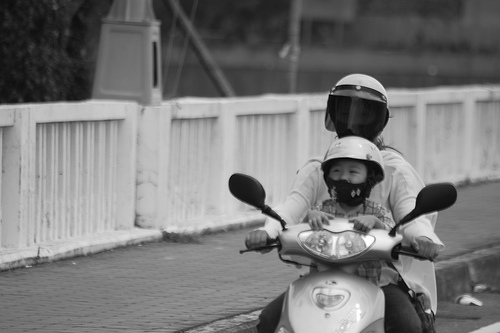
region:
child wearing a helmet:
[313, 134, 385, 209]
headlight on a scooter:
[295, 226, 377, 267]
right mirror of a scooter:
[223, 169, 288, 230]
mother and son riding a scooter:
[238, 68, 450, 317]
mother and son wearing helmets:
[321, 66, 391, 206]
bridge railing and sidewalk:
[35, 100, 224, 292]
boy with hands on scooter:
[305, 137, 390, 236]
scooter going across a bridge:
[220, 46, 460, 327]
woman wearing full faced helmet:
[320, 67, 392, 139]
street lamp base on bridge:
[87, 3, 171, 109]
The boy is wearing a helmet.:
[311, 137, 391, 211]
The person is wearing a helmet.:
[316, 67, 393, 135]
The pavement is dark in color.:
[77, 274, 158, 316]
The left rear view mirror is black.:
[415, 179, 461, 218]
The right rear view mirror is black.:
[222, 167, 269, 212]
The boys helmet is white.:
[317, 132, 391, 171]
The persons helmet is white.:
[326, 64, 387, 101]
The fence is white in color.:
[18, 112, 145, 242]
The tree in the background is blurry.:
[7, 11, 77, 85]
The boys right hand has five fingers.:
[303, 210, 335, 230]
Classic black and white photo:
[7, 6, 484, 326]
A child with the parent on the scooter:
[201, 70, 463, 332]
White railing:
[3, 83, 495, 265]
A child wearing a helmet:
[318, 133, 391, 209]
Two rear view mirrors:
[215, 162, 461, 226]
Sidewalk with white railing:
[6, 173, 495, 327]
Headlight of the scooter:
[272, 219, 402, 259]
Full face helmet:
[319, 67, 398, 148]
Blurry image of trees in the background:
[1, 3, 112, 103]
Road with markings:
[421, 273, 497, 330]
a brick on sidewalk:
[12, 277, 27, 289]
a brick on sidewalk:
[44, 268, 63, 281]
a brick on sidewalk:
[69, 281, 84, 296]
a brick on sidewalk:
[78, 297, 95, 321]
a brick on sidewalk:
[100, 306, 108, 320]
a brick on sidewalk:
[137, 281, 157, 302]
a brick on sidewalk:
[181, 294, 199, 310]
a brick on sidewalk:
[207, 286, 219, 297]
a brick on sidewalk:
[187, 263, 199, 271]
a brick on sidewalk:
[220, 273, 242, 292]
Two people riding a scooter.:
[227, 74, 457, 331]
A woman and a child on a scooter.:
[223, 71, 462, 331]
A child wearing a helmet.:
[255, 137, 422, 332]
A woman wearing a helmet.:
[242, 71, 439, 332]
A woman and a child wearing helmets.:
[226, 68, 458, 332]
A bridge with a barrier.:
[1, 82, 498, 332]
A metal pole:
[89, 0, 162, 107]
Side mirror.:
[227, 172, 287, 229]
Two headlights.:
[299, 224, 376, 263]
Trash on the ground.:
[453, 279, 495, 308]